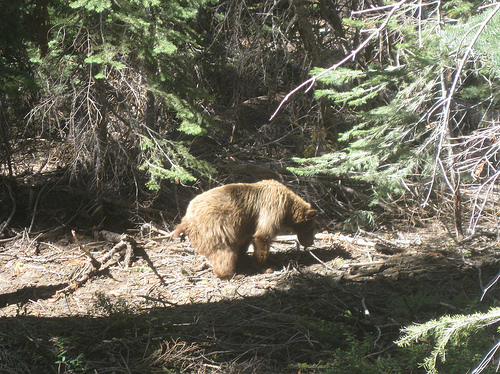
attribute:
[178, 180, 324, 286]
bear — brown, squatting, looking down, large, going potty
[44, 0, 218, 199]
tree — pine, bare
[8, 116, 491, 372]
ground — light brown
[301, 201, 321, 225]
ears — perked, perked up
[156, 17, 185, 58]
leaves — green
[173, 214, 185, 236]
tail — small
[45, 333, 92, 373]
fern — green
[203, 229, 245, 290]
legs — thick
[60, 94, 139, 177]
limbs — brown